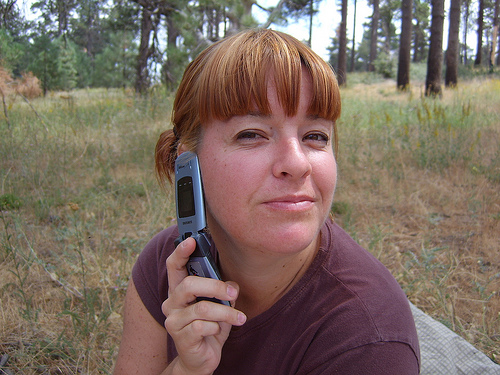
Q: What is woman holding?
A: Cell phone.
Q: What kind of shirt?
A: Tshirt.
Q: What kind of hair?
A: Red.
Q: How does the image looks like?
A: Funny.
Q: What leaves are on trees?
A: Green.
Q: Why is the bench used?
A: Sit.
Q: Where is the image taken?
A: Park.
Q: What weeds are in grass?
A: Brown.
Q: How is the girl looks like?
A: Smiling.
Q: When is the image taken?
A: Girls smiling.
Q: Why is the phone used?
A: Communicate.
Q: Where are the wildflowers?
A: In the clearing.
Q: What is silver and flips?
A: The phone.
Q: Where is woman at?
A: A wooded park.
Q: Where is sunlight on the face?
A: The left.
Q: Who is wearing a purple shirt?
A: The woman.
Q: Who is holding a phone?
A: The woman.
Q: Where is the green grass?
A: In the woods.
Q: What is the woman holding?
A: Cell phone.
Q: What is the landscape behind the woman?
A: Grassy.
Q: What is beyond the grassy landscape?
A: Wooded area.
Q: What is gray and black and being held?
A: Cell phone.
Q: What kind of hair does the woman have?
A: Red.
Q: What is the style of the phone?
A: Flip style.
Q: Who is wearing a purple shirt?
A: Red haired lady.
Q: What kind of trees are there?
A: Tall green.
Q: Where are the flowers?
A: Behind the right shoulder.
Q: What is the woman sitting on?
A: Gray sheet.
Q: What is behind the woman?
A: Trees and grass.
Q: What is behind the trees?
A: A sky.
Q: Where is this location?
A: Field.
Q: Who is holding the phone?
A: A woman.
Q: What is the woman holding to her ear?
A: Cell phone.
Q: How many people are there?
A: One.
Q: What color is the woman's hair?
A: Red.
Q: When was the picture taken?
A: Daytime.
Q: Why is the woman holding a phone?
A: Making a call.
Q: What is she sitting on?
A: A blanket.